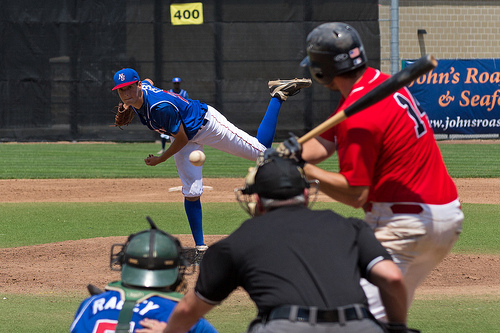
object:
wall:
[1, 2, 380, 139]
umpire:
[128, 154, 417, 333]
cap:
[111, 69, 141, 92]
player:
[253, 20, 467, 330]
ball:
[188, 149, 207, 167]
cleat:
[266, 78, 313, 102]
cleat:
[194, 244, 210, 265]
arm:
[157, 110, 190, 162]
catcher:
[66, 212, 222, 332]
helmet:
[108, 215, 206, 290]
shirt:
[317, 66, 460, 206]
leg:
[172, 144, 205, 247]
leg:
[203, 99, 284, 163]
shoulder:
[148, 96, 182, 127]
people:
[128, 152, 413, 332]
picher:
[111, 67, 314, 269]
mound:
[0, 233, 500, 301]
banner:
[399, 57, 499, 133]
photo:
[0, 0, 500, 333]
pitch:
[108, 66, 316, 269]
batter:
[251, 20, 467, 323]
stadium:
[0, 0, 500, 333]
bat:
[294, 50, 441, 146]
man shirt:
[191, 203, 396, 317]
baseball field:
[0, 138, 497, 333]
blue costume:
[137, 79, 210, 141]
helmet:
[298, 20, 370, 86]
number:
[173, 8, 183, 20]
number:
[391, 86, 428, 139]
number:
[90, 317, 135, 332]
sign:
[166, 1, 206, 26]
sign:
[399, 57, 497, 139]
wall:
[378, 4, 498, 134]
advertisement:
[403, 58, 500, 131]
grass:
[0, 137, 500, 180]